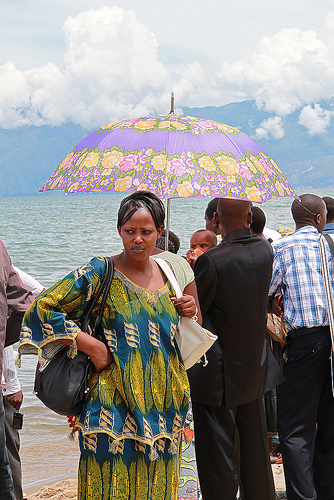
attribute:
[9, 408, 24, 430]
camera — digital, black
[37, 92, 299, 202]
umbrella —   purple,  open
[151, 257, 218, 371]
purse —   two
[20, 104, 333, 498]
people — in a crowd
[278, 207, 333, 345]
shirt —  plaid,  blue and white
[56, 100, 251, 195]
colored umbrella —  floral colored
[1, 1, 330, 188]
sky —   blue,  blue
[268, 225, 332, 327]
shirt —  blue and white 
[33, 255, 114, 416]
handbag —  leather,  black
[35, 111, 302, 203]
umbrella —   woman's,   colorful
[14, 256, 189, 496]
dress —  african,  blue and green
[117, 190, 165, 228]
black hair —  black,  short 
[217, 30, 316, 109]
clouds —  white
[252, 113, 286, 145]
cloud —  white 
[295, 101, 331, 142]
cloud —  white 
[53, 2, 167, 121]
cloud —  white 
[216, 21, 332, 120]
cloud —  white 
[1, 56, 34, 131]
cloud —  white 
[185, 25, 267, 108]
clouds —  white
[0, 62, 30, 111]
cloud — white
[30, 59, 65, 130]
cloud — white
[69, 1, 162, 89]
cloud — white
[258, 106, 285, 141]
cloud — white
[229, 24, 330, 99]
cloud — white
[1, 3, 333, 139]
sky —  blue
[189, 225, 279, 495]
suit — tuxedo, black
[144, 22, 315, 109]
clouds —  white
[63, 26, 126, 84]
clouds —  white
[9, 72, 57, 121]
clouds —  white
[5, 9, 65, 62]
sky —  blue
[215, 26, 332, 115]
clouds —  white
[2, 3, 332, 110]
sky —  blue,   blue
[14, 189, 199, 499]
she —  upset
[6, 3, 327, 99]
sky —   blue,  blue 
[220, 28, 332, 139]
clouds —  white